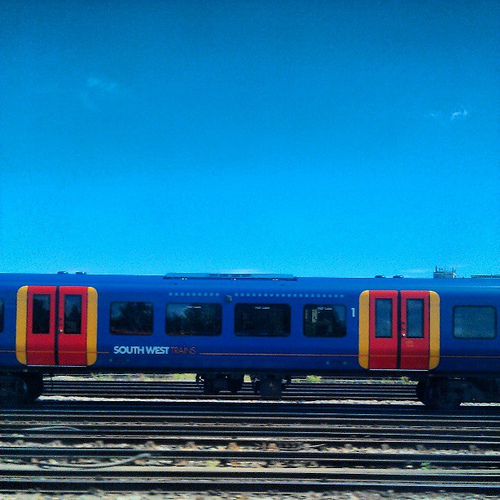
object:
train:
[2, 266, 498, 408]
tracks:
[6, 378, 499, 499]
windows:
[30, 292, 51, 334]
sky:
[0, 1, 499, 274]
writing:
[113, 345, 196, 355]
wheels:
[3, 366, 46, 415]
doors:
[16, 281, 99, 367]